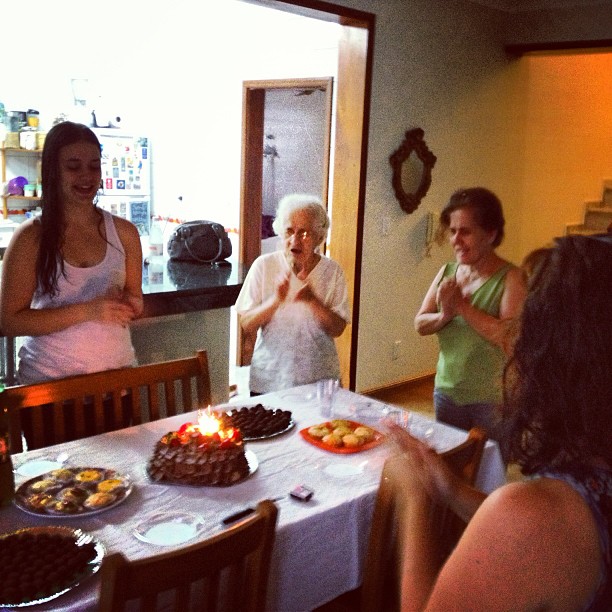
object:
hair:
[272, 194, 330, 242]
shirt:
[432, 257, 520, 410]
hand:
[291, 269, 311, 304]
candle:
[185, 398, 228, 440]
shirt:
[14, 207, 140, 389]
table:
[0, 376, 505, 612]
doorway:
[239, 77, 335, 373]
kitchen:
[0, 0, 612, 612]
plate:
[11, 466, 131, 520]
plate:
[299, 419, 389, 454]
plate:
[217, 404, 296, 441]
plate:
[0, 524, 107, 612]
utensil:
[222, 495, 287, 526]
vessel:
[318, 378, 336, 419]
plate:
[132, 511, 205, 548]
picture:
[401, 149, 424, 195]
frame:
[388, 127, 438, 214]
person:
[0, 122, 143, 454]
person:
[236, 194, 350, 398]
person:
[413, 186, 526, 475]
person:
[383, 235, 612, 612]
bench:
[0, 347, 214, 465]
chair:
[97, 500, 277, 612]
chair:
[362, 421, 493, 612]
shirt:
[233, 251, 351, 393]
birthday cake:
[145, 404, 250, 487]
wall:
[351, 0, 529, 395]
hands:
[436, 275, 474, 321]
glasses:
[285, 226, 313, 239]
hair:
[25, 123, 124, 302]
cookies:
[309, 419, 376, 447]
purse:
[167, 219, 232, 264]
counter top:
[134, 253, 254, 320]